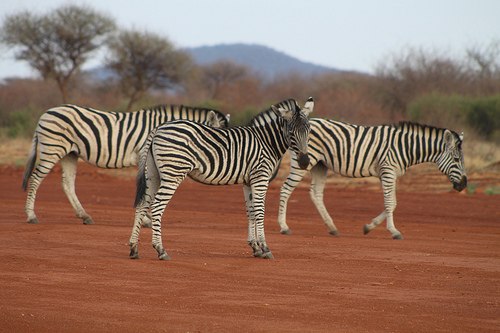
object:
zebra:
[20, 102, 230, 226]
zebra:
[127, 96, 314, 261]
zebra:
[273, 117, 467, 240]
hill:
[60, 43, 383, 98]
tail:
[20, 128, 35, 190]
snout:
[295, 153, 311, 167]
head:
[267, 95, 319, 170]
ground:
[1, 138, 499, 332]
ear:
[270, 104, 287, 120]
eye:
[451, 156, 459, 161]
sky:
[0, 0, 499, 81]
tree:
[0, 4, 116, 104]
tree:
[101, 28, 193, 110]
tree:
[188, 58, 248, 115]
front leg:
[249, 178, 272, 259]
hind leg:
[126, 160, 151, 259]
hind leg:
[146, 162, 187, 262]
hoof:
[73, 214, 94, 224]